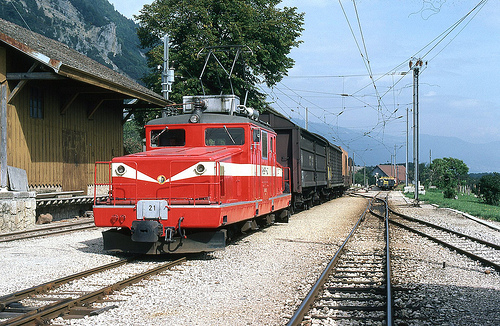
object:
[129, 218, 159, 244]
attachment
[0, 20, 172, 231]
waiting area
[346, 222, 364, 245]
tracks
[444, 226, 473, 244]
tracks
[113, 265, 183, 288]
tracks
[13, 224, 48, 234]
tracks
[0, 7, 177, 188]
building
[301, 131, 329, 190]
cars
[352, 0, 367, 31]
wires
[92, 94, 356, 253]
train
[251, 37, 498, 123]
clouds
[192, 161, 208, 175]
light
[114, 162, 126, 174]
train light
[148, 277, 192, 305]
rocks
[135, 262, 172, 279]
train tracks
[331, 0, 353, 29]
power lines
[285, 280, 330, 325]
train tracks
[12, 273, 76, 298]
train tracks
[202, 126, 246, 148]
left window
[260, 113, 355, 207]
cargo unit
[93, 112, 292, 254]
train engine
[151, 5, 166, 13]
leaves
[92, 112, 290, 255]
front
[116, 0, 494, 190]
sky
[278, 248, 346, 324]
tracks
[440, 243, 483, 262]
tracks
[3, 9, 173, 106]
roof